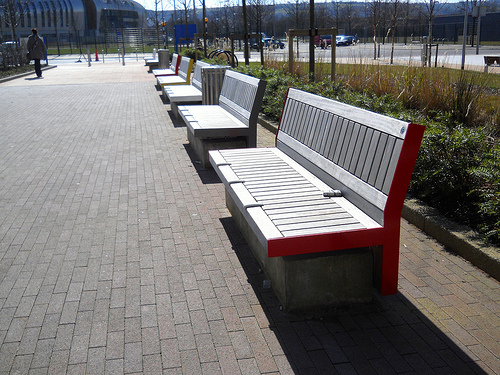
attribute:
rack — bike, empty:
[198, 37, 256, 87]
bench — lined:
[175, 89, 472, 281]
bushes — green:
[172, 46, 499, 245]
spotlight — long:
[203, 16, 208, 22]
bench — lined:
[221, 80, 416, 303]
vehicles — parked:
[239, 27, 356, 50]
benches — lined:
[139, 52, 396, 298]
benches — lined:
[208, 85, 418, 265]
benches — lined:
[175, 62, 270, 139]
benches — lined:
[156, 49, 206, 104]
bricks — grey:
[153, 293, 175, 340]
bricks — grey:
[176, 324, 198, 351]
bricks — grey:
[184, 290, 201, 310]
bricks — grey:
[108, 306, 125, 331]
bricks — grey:
[124, 341, 142, 372]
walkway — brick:
[3, 60, 499, 373]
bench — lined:
[144, 46, 156, 64]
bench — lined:
[151, 56, 181, 75]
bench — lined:
[154, 55, 194, 85]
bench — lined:
[161, 57, 211, 99]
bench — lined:
[174, 70, 264, 175]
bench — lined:
[201, 83, 422, 334]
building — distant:
[0, 0, 150, 45]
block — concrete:
[212, 181, 374, 324]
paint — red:
[387, 205, 398, 248]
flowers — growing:
[372, 28, 496, 97]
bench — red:
[232, 107, 408, 297]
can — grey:
[183, 46, 220, 101]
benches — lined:
[183, 61, 428, 303]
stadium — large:
[1, 3, 186, 55]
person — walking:
[23, 27, 50, 77]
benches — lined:
[151, 43, 415, 290]